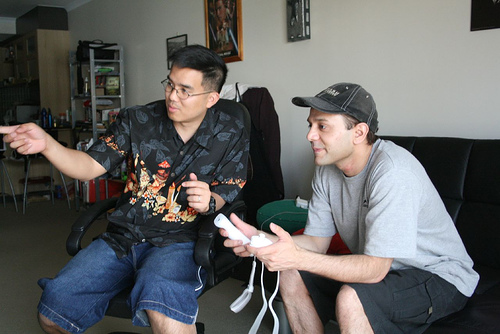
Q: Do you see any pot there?
A: No, there are no pots.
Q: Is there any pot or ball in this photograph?
A: No, there are no pots or balls.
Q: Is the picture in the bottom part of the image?
A: No, the picture is in the top of the image.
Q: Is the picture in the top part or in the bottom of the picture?
A: The picture is in the top of the image.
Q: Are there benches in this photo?
A: No, there are no benches.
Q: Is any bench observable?
A: No, there are no benches.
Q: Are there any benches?
A: No, there are no benches.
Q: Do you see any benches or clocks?
A: No, there are no benches or clocks.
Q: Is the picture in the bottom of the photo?
A: No, the picture is in the top of the image.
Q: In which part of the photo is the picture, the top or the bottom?
A: The picture is in the top of the image.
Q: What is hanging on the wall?
A: The picture is hanging on the wall.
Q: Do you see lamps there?
A: No, there are no lamps.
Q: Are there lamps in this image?
A: No, there are no lamps.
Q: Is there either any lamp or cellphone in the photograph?
A: No, there are no lamps or cell phones.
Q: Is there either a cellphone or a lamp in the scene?
A: No, there are no lamps or cell phones.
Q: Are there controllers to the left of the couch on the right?
A: Yes, there is a controller to the left of the couch.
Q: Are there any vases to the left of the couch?
A: No, there is a controller to the left of the couch.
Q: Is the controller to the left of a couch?
A: Yes, the controller is to the left of a couch.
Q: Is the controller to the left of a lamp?
A: No, the controller is to the left of a couch.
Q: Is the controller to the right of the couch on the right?
A: No, the controller is to the left of the couch.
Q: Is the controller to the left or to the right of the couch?
A: The controller is to the left of the couch.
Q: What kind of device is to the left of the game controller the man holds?
A: The device is a controller.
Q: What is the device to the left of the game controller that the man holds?
A: The device is a controller.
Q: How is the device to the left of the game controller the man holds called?
A: The device is a controller.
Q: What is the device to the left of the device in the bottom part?
A: The device is a controller.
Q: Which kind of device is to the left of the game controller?
A: The device is a controller.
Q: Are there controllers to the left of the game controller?
A: Yes, there is a controller to the left of the game controller.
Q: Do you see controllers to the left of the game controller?
A: Yes, there is a controller to the left of the game controller.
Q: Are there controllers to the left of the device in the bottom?
A: Yes, there is a controller to the left of the game controller.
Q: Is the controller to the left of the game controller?
A: Yes, the controller is to the left of the game controller.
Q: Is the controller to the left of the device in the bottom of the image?
A: Yes, the controller is to the left of the game controller.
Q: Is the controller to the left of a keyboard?
A: No, the controller is to the left of the game controller.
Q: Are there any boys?
A: No, there are no boys.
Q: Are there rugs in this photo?
A: No, there are no rugs.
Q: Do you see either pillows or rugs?
A: No, there are no rugs or pillows.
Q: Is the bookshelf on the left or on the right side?
A: The bookshelf is on the left of the image.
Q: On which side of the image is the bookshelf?
A: The bookshelf is on the left of the image.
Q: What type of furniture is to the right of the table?
A: The piece of furniture is a bookshelf.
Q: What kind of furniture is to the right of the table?
A: The piece of furniture is a bookshelf.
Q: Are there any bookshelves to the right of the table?
A: Yes, there is a bookshelf to the right of the table.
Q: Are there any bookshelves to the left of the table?
A: No, the bookshelf is to the right of the table.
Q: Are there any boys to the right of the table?
A: No, there is a bookshelf to the right of the table.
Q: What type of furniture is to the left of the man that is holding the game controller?
A: The piece of furniture is a bookshelf.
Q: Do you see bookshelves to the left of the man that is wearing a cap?
A: Yes, there is a bookshelf to the left of the man.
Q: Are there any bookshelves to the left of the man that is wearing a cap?
A: Yes, there is a bookshelf to the left of the man.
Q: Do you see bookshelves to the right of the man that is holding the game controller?
A: No, the bookshelf is to the left of the man.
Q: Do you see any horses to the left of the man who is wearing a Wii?
A: No, there is a bookshelf to the left of the man.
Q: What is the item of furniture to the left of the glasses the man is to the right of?
A: The piece of furniture is a bookshelf.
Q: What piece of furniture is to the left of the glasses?
A: The piece of furniture is a bookshelf.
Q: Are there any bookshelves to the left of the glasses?
A: Yes, there is a bookshelf to the left of the glasses.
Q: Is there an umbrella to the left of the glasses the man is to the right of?
A: No, there is a bookshelf to the left of the glasses.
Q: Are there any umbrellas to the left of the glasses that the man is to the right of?
A: No, there is a bookshelf to the left of the glasses.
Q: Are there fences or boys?
A: No, there are no fences or boys.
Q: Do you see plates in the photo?
A: No, there are no plates.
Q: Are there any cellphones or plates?
A: No, there are no plates or cellphones.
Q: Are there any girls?
A: No, there are no girls.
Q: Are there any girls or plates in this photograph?
A: No, there are no girls or plates.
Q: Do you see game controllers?
A: Yes, there is a game controller.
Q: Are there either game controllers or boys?
A: Yes, there is a game controller.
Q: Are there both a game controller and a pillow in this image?
A: No, there is a game controller but no pillows.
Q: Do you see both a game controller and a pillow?
A: No, there is a game controller but no pillows.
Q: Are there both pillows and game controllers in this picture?
A: No, there is a game controller but no pillows.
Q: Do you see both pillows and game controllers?
A: No, there is a game controller but no pillows.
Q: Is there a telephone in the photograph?
A: No, there are no phones.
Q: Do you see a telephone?
A: No, there are no phones.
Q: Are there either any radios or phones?
A: No, there are no phones or radios.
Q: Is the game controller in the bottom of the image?
A: Yes, the game controller is in the bottom of the image.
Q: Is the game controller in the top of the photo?
A: No, the game controller is in the bottom of the image.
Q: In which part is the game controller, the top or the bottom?
A: The game controller is in the bottom of the image.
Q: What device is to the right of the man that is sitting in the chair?
A: The device is a game controller.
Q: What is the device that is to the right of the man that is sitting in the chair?
A: The device is a game controller.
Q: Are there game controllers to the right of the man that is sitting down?
A: Yes, there is a game controller to the right of the man.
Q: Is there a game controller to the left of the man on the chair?
A: No, the game controller is to the right of the man.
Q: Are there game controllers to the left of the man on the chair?
A: No, the game controller is to the right of the man.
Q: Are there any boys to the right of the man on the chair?
A: No, there is a game controller to the right of the man.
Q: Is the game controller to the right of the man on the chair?
A: Yes, the game controller is to the right of the man.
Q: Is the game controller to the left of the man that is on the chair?
A: No, the game controller is to the right of the man.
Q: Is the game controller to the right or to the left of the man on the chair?
A: The game controller is to the right of the man.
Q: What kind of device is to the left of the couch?
A: The device is a game controller.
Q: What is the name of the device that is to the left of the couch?
A: The device is a game controller.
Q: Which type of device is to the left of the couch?
A: The device is a game controller.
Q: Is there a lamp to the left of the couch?
A: No, there is a game controller to the left of the couch.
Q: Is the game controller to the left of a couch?
A: Yes, the game controller is to the left of a couch.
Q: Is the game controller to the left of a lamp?
A: No, the game controller is to the left of a couch.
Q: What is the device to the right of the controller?
A: The device is a game controller.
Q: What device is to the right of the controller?
A: The device is a game controller.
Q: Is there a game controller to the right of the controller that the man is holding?
A: Yes, there is a game controller to the right of the controller.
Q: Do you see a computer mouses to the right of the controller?
A: No, there is a game controller to the right of the controller.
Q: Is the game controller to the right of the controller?
A: Yes, the game controller is to the right of the controller.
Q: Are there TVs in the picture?
A: No, there are no tvs.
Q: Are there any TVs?
A: No, there are no tvs.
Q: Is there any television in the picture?
A: No, there are no televisions.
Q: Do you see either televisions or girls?
A: No, there are no televisions or girls.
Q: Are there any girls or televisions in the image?
A: No, there are no televisions or girls.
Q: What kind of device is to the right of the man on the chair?
A: The device is a Wii.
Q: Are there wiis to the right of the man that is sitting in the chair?
A: Yes, there is a Wii to the right of the man.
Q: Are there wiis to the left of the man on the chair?
A: No, the Wii is to the right of the man.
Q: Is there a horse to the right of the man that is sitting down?
A: No, there is a Wii to the right of the man.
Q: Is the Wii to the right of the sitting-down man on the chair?
A: Yes, the Wii is to the right of the man.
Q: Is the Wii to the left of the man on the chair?
A: No, the Wii is to the right of the man.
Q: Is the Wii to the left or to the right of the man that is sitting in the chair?
A: The Wii is to the right of the man.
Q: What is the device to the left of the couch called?
A: The device is a Wii.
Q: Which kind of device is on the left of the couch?
A: The device is a Wii.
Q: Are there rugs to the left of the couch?
A: No, there is a Wii to the left of the couch.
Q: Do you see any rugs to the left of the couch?
A: No, there is a Wii to the left of the couch.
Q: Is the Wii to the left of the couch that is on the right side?
A: Yes, the Wii is to the left of the couch.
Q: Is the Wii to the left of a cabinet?
A: No, the Wii is to the left of the couch.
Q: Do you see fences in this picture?
A: No, there are no fences.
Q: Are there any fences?
A: No, there are no fences.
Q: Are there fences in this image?
A: No, there are no fences.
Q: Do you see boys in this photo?
A: No, there are no boys.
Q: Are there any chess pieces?
A: No, there are no chess pieces.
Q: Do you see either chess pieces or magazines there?
A: No, there are no chess pieces or magazines.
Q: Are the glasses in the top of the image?
A: Yes, the glasses are in the top of the image.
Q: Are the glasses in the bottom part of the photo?
A: No, the glasses are in the top of the image.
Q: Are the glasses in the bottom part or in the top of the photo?
A: The glasses are in the top of the image.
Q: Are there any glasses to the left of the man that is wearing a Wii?
A: Yes, there are glasses to the left of the man.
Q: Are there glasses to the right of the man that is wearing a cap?
A: No, the glasses are to the left of the man.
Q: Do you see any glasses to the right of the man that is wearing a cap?
A: No, the glasses are to the left of the man.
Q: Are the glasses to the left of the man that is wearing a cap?
A: Yes, the glasses are to the left of the man.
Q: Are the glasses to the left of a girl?
A: No, the glasses are to the left of the man.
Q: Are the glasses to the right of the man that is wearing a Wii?
A: No, the glasses are to the left of the man.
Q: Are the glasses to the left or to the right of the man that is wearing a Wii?
A: The glasses are to the left of the man.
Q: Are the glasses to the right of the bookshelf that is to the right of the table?
A: Yes, the glasses are to the right of the bookshelf.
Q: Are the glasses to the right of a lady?
A: No, the glasses are to the right of the bookshelf.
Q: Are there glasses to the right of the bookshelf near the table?
A: Yes, there are glasses to the right of the bookshelf.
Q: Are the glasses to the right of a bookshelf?
A: Yes, the glasses are to the right of a bookshelf.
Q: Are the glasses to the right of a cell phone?
A: No, the glasses are to the right of a bookshelf.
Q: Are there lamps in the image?
A: No, there are no lamps.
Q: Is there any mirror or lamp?
A: No, there are no lamps or mirrors.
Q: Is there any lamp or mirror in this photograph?
A: No, there are no lamps or mirrors.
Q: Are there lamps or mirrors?
A: No, there are no lamps or mirrors.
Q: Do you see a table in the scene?
A: Yes, there is a table.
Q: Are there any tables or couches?
A: Yes, there is a table.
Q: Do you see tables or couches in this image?
A: Yes, there is a table.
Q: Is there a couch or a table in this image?
A: Yes, there is a table.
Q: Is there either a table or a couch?
A: Yes, there is a table.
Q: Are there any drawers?
A: No, there are no drawers.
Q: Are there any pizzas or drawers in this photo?
A: No, there are no drawers or pizzas.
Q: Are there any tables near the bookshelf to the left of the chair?
A: Yes, there is a table near the bookshelf.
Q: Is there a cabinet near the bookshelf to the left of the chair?
A: No, there is a table near the bookshelf.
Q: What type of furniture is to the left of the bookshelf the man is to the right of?
A: The piece of furniture is a table.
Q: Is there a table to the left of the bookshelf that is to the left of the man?
A: Yes, there is a table to the left of the bookshelf.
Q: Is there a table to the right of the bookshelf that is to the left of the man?
A: No, the table is to the left of the bookshelf.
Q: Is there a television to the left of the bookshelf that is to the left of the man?
A: No, there is a table to the left of the bookshelf.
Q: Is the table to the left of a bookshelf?
A: Yes, the table is to the left of a bookshelf.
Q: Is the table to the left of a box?
A: No, the table is to the left of a bookshelf.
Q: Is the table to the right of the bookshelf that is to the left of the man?
A: No, the table is to the left of the bookshelf.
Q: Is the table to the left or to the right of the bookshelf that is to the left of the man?
A: The table is to the left of the bookshelf.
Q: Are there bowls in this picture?
A: No, there are no bowls.